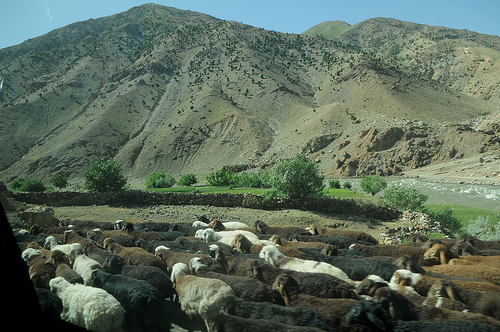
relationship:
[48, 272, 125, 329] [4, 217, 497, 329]
sheep walking in herd